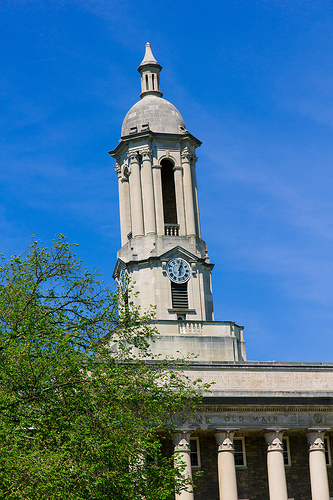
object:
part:
[137, 41, 163, 99]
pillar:
[141, 151, 156, 237]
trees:
[0, 230, 203, 500]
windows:
[232, 437, 246, 467]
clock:
[165, 256, 191, 285]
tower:
[91, 71, 247, 363]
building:
[89, 39, 333, 500]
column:
[181, 161, 197, 235]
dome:
[119, 94, 186, 137]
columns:
[129, 153, 145, 237]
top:
[145, 41, 151, 48]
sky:
[214, 24, 312, 272]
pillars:
[116, 153, 130, 248]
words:
[205, 413, 280, 424]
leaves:
[38, 298, 96, 384]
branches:
[40, 252, 79, 284]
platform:
[165, 223, 181, 237]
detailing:
[127, 149, 139, 158]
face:
[166, 258, 192, 283]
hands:
[178, 262, 183, 271]